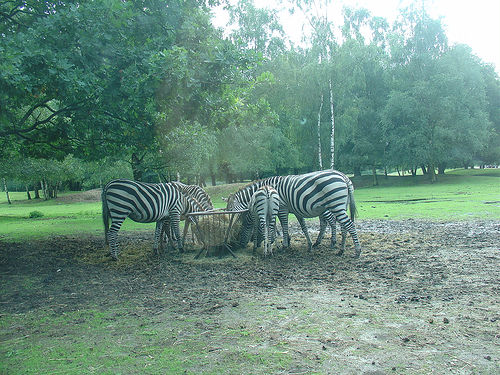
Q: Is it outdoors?
A: Yes, it is outdoors.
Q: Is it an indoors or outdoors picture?
A: It is outdoors.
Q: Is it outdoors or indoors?
A: It is outdoors.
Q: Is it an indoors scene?
A: No, it is outdoors.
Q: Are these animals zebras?
A: Yes, all the animals are zebras.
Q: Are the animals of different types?
A: No, all the animals are zebras.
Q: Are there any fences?
A: No, there are no fences.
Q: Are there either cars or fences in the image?
A: No, there are no fences or cars.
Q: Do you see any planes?
A: No, there are no planes.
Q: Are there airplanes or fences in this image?
A: No, there are no airplanes or fences.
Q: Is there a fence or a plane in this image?
A: No, there are no airplanes or fences.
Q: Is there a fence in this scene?
A: No, there are no fences.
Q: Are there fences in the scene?
A: No, there are no fences.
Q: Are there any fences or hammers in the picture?
A: No, there are no fences or hammers.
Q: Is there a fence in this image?
A: No, there are no fences.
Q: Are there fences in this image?
A: No, there are no fences.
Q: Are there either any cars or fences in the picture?
A: No, there are no fences or cars.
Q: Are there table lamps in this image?
A: No, there are no table lamps.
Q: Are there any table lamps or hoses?
A: No, there are no table lamps or hoses.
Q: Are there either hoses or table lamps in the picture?
A: No, there are no table lamps or hoses.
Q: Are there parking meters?
A: No, there are no parking meters.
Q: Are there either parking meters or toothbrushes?
A: No, there are no parking meters or toothbrushes.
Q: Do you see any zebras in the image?
A: Yes, there is a zebra.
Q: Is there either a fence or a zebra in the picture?
A: Yes, there is a zebra.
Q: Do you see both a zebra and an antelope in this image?
A: No, there is a zebra but no antelopes.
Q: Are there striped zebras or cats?
A: Yes, there is a striped zebra.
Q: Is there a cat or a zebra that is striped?
A: Yes, the zebra is striped.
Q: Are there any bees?
A: No, there are no bees.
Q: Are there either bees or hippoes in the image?
A: No, there are no bees or hippoes.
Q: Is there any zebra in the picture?
A: Yes, there is a zebra.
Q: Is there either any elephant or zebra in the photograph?
A: Yes, there is a zebra.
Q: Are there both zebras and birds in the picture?
A: No, there is a zebra but no birds.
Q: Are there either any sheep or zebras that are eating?
A: Yes, the zebra is eating.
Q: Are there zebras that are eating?
A: Yes, there is a zebra that is eating.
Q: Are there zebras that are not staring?
A: Yes, there is a zebra that is eating.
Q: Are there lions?
A: No, there are no lions.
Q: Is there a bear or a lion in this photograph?
A: No, there are no lions or bears.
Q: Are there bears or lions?
A: No, there are no lions or bears.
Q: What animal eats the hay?
A: The zebra eats the hay.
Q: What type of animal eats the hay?
A: The animal is a zebra.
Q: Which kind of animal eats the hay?
A: The animal is a zebra.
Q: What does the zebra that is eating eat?
A: The zebra eats hay.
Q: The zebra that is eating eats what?
A: The zebra eats hay.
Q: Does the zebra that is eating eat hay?
A: Yes, the zebra eats hay.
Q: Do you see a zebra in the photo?
A: Yes, there is a zebra.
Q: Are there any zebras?
A: Yes, there is a zebra.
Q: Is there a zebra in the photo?
A: Yes, there is a zebra.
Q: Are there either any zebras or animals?
A: Yes, there is a zebra.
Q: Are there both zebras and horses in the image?
A: No, there is a zebra but no horses.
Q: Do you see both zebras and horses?
A: No, there is a zebra but no horses.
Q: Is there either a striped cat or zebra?
A: Yes, there is a striped zebra.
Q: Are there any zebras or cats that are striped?
A: Yes, the zebra is striped.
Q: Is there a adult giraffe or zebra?
A: Yes, there is an adult zebra.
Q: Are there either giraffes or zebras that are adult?
A: Yes, the zebra is adult.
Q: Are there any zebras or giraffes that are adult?
A: Yes, the zebra is adult.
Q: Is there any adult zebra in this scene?
A: Yes, there is an adult zebra.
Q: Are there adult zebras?
A: Yes, there is an adult zebra.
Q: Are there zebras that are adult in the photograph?
A: Yes, there is an adult zebra.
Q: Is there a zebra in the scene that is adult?
A: Yes, there is a zebra that is adult.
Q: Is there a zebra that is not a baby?
A: Yes, there is a adult zebra.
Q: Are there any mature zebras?
A: Yes, there is a mature zebra.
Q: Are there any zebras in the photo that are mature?
A: Yes, there is a zebra that is mature.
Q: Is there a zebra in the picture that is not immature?
A: Yes, there is an mature zebra.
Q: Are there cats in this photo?
A: No, there are no cats.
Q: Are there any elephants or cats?
A: No, there are no cats or elephants.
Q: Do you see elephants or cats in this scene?
A: No, there are no cats or elephants.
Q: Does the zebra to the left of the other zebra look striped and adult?
A: Yes, the zebra is striped and adult.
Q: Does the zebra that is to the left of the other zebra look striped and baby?
A: No, the zebra is striped but adult.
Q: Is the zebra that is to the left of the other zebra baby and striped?
A: No, the zebra is striped but adult.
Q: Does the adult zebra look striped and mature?
A: Yes, the zebra is striped and mature.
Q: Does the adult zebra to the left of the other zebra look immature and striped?
A: No, the zebra is striped but mature.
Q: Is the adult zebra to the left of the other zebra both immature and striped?
A: No, the zebra is striped but mature.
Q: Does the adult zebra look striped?
A: Yes, the zebra is striped.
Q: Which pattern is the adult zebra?
A: The zebra is striped.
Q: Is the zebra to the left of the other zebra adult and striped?
A: Yes, the zebra is adult and striped.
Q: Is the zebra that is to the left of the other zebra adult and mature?
A: Yes, the zebra is adult and mature.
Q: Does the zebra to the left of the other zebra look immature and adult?
A: No, the zebra is adult but mature.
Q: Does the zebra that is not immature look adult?
A: Yes, the zebra is adult.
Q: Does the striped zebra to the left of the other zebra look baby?
A: No, the zebra is adult.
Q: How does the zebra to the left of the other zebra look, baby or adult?
A: The zebra is adult.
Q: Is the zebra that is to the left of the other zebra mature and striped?
A: Yes, the zebra is mature and striped.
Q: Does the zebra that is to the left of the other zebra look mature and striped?
A: Yes, the zebra is mature and striped.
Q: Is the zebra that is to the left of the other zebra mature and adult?
A: Yes, the zebra is mature and adult.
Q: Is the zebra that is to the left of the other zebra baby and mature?
A: No, the zebra is mature but adult.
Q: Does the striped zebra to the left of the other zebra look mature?
A: Yes, the zebra is mature.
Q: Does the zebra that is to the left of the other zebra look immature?
A: No, the zebra is mature.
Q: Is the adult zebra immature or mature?
A: The zebra is mature.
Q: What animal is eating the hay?
A: The zebra is eating the hay.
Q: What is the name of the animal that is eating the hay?
A: The animal is a zebra.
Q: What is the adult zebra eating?
A: The zebra is eating hay.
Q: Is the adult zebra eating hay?
A: Yes, the zebra is eating hay.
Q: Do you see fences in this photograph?
A: No, there are no fences.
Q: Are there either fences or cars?
A: No, there are no fences or cars.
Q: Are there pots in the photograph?
A: No, there are no pots.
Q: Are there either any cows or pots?
A: No, there are no pots or cows.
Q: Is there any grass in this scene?
A: Yes, there is grass.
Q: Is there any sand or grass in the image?
A: Yes, there is grass.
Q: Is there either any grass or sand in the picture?
A: Yes, there is grass.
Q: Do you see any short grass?
A: Yes, there is short grass.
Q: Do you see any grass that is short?
A: Yes, there is grass that is short.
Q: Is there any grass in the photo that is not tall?
A: Yes, there is short grass.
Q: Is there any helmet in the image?
A: No, there are no helmets.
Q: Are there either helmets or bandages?
A: No, there are no helmets or bandages.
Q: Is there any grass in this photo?
A: Yes, there is grass.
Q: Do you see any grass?
A: Yes, there is grass.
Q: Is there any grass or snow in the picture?
A: Yes, there is grass.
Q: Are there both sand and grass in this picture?
A: No, there is grass but no sand.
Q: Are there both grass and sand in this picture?
A: No, there is grass but no sand.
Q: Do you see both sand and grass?
A: No, there is grass but no sand.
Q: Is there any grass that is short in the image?
A: Yes, there is short grass.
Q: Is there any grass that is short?
A: Yes, there is grass that is short.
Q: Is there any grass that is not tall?
A: Yes, there is short grass.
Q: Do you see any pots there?
A: No, there are no pots.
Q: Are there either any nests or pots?
A: No, there are no pots or nests.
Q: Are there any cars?
A: No, there are no cars.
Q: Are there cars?
A: No, there are no cars.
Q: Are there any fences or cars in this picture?
A: No, there are no cars or fences.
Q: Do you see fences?
A: No, there are no fences.